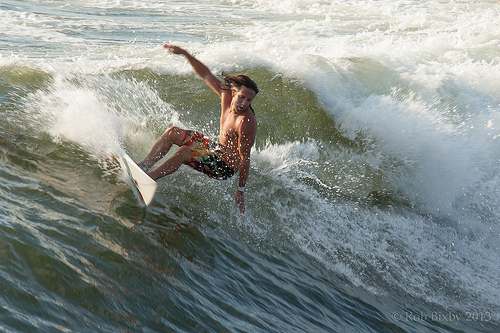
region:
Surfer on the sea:
[84, 25, 283, 226]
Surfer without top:
[98, 36, 282, 230]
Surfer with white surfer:
[98, 38, 276, 225]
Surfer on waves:
[11, 21, 498, 275]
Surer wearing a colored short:
[101, 29, 266, 219]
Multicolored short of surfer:
[178, 123, 243, 179]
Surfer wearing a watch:
[108, 37, 267, 233]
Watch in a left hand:
[231, 179, 253, 196]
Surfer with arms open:
[81, 26, 304, 226]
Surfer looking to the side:
[100, 37, 280, 228]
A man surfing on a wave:
[70, 31, 295, 242]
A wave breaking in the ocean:
[302, 40, 487, 260]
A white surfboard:
[85, 130, 171, 215]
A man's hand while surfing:
[153, 31, 200, 65]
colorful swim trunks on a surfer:
[164, 115, 257, 194]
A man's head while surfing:
[217, 67, 262, 127]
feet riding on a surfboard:
[93, 100, 197, 219]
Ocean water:
[31, 242, 230, 324]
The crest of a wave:
[144, 46, 357, 81]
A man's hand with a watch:
[223, 178, 266, 227]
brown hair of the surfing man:
[216, 72, 261, 89]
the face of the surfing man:
[232, 80, 253, 117]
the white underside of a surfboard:
[117, 147, 157, 209]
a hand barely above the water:
[235, 182, 252, 230]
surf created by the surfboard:
[67, 84, 157, 164]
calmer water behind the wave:
[31, 7, 251, 47]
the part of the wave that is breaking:
[297, 56, 499, 141]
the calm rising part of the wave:
[12, 127, 269, 303]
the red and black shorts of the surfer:
[182, 130, 237, 181]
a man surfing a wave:
[122, 30, 254, 209]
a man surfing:
[110, 37, 262, 236]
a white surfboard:
[94, 129, 162, 224]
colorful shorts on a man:
[167, 122, 239, 184]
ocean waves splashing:
[263, 10, 496, 329]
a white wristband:
[234, 180, 252, 215]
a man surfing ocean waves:
[101, 30, 400, 236]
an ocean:
[267, 5, 497, 329]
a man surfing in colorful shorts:
[107, 34, 267, 251]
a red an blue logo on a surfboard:
[126, 173, 150, 206]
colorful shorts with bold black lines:
[177, 123, 238, 194]